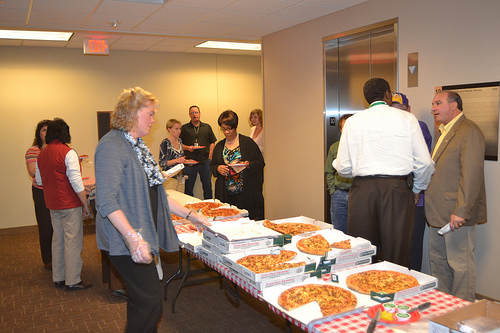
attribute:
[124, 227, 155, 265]
glove — clear, plastic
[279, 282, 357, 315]
pizza — round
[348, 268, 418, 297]
pizza — round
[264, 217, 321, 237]
pizza — round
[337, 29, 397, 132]
elevator doors — silver, closed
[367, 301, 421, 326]
plate — red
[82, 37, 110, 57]
exit sign — red, white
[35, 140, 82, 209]
vest — red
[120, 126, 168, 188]
scarf — floral, black, white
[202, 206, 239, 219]
pizza — round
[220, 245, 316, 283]
box — white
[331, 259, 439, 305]
box — white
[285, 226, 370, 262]
box — white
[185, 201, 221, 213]
pizza — round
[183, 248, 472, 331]
tablecloth — checkered, red, white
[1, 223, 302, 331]
floor — brown, carpeted